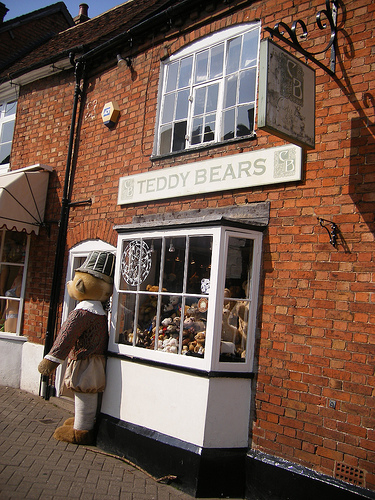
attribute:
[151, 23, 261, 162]
window — glass, large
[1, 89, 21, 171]
window — glass, old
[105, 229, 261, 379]
window — glass, large, bay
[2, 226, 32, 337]
window — glass, large, bay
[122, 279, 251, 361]
animals — stuffed, cluster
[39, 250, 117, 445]
bear — stuffed, large, teddy, standing, display, lifesize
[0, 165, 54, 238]
awning — white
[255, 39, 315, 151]
sign — store sign, old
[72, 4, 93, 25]
chimney — on top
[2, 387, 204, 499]
sidewalk — brick, paved, grey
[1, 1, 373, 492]
wall — brick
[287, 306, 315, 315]
brick — red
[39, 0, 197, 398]
pipes — metal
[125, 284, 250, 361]
bears — teddy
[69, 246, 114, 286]
hat — black, white, striped, bucket, grey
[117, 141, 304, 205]
sign — white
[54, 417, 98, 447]
feet — brown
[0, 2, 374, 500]
building — brick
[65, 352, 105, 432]
leg — white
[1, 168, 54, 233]
canopy — white, black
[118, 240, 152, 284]
design — circle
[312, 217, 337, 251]
fixture — small, wrought iron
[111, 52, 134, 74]
light — spotlight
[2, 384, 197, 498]
ground — brick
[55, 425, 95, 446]
foot — furry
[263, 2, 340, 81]
scrollwork — wrought iron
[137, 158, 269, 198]
word — bears